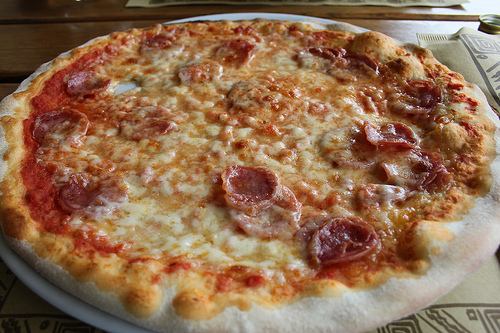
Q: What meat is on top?
A: Pepperoni.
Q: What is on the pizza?
A: Cheese.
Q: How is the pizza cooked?
A: Baked.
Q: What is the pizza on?
A: Plate.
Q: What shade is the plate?
A: White.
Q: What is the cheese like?
A: Melted.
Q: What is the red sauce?
A: Tomato sauce.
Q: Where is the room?
A: Kitchen.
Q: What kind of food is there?
A: Pizza.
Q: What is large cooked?
A: Pizza.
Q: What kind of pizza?
A: Cheese and meat.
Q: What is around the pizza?
A: Crust.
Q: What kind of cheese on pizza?
A: Mozzarella.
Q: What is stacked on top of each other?
A: Pepperoni.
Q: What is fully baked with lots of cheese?
A: Pizza.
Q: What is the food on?
A: Wooden table.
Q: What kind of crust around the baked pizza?
A: Puffy.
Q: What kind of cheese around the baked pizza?
A: Melted mozzarella.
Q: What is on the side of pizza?
A: Dose of tomato.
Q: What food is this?
A: Pizza.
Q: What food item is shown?
A: Pizza.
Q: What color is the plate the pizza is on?
A: White.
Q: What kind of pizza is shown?
A: Meat pizza.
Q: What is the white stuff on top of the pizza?
A: Cheese.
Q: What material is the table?
A: Wood.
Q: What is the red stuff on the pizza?
A: Sauce.